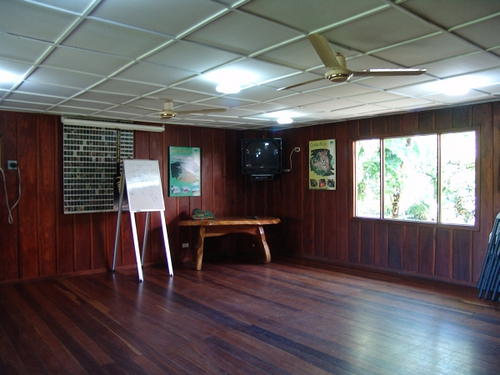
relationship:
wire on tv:
[281, 124, 305, 188] [222, 119, 296, 201]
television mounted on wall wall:
[239, 137, 283, 183] [2, 122, 292, 282]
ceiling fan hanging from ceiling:
[277, 33, 425, 92] [1, 2, 497, 127]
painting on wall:
[308, 139, 337, 191] [261, 97, 498, 299]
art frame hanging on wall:
[171, 142, 199, 200] [0, 112, 268, 284]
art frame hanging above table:
[171, 142, 199, 200] [179, 213, 277, 273]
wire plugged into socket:
[2, 172, 44, 237] [11, 160, 18, 170]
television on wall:
[239, 137, 283, 183] [278, 138, 423, 279]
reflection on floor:
[345, 309, 475, 374] [5, 243, 498, 373]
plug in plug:
[179, 240, 190, 249] [182, 244, 190, 249]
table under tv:
[178, 216, 281, 270] [237, 137, 282, 175]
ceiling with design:
[1, 2, 497, 127] [108, 20, 367, 120]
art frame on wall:
[168, 146, 202, 197] [142, 125, 278, 254]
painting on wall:
[311, 143, 338, 191] [261, 97, 498, 299]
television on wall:
[238, 135, 288, 180] [0, 112, 268, 284]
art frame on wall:
[168, 146, 202, 197] [0, 103, 498, 295]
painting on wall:
[308, 139, 337, 191] [248, 110, 490, 295]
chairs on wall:
[478, 209, 498, 305] [261, 97, 498, 299]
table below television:
[173, 212, 283, 272] [215, 119, 322, 206]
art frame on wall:
[168, 146, 202, 197] [0, 112, 268, 284]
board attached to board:
[121, 148, 174, 219] [123, 160, 165, 213]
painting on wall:
[308, 139, 337, 191] [10, 125, 49, 267]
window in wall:
[350, 141, 474, 222] [10, 125, 49, 267]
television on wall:
[239, 137, 283, 183] [265, 137, 402, 254]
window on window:
[354, 131, 482, 232] [344, 121, 478, 222]